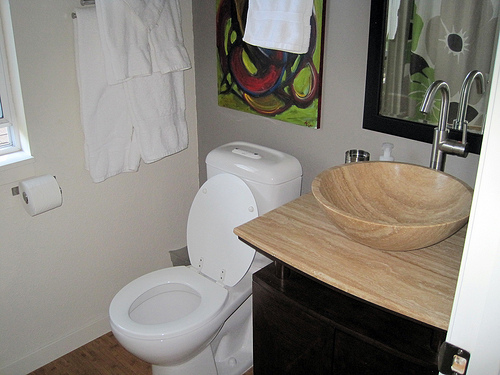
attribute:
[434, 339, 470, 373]
door latch — brass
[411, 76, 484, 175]
faucet — large, silver, sink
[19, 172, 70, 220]
toilet paper — white 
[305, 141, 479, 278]
sink — wooden bowl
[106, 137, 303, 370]
toilet — white 